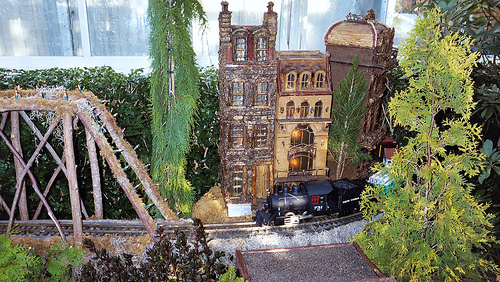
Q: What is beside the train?
A: A house.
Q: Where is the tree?
A: Beside the train.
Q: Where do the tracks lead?
A: To the bridge.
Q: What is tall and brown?
A: Building.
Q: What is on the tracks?
A: Train.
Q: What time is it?
A: Afternoon.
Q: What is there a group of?
A: Model buildings.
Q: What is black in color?
A: The train.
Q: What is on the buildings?
A: Windows.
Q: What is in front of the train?
A: A bridge.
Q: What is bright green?
A: The tree.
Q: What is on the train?
A: Wheels.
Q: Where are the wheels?
A: On the train.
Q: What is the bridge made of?
A: Wood.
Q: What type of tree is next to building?
A: Evergreen.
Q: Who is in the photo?
A: No one.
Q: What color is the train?
A: Black and red.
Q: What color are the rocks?
A: Gray.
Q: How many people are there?
A: None.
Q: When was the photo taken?
A: Daytime.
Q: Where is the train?
A: On the track.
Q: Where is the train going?
A: To a bridge.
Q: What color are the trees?
A: Green.